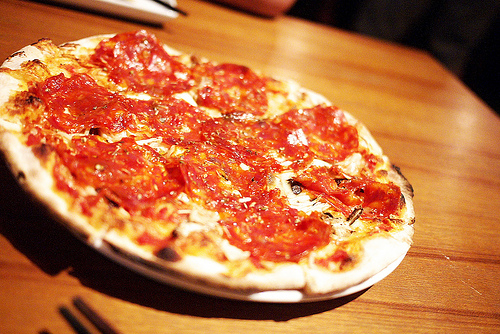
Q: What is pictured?
A: Pizza.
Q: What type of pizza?
A: Pepperoni.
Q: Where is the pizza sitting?
A: On a wooden table.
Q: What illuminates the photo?
A: Indoor lighting.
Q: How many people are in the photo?
A: None.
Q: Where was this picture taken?
A: Maybe a restaurant.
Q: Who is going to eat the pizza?
A: The patrons.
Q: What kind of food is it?
A: Pizza.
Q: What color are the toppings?
A: Red.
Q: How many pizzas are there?
A: One.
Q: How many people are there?
A: None.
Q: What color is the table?
A: Brown.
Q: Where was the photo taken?
A: Inside somewhere.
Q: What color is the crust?
A: Brown.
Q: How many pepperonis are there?
A: More than three.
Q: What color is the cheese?
A: White.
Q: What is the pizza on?
A: Dish.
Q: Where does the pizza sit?
A: On a white dish.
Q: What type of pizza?
A: Pepperoni, cheese and herb.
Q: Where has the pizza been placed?
A: On a plate.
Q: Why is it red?
A: Sauce.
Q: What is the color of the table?
A: Brown.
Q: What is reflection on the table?
A: Light.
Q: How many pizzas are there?
A: 1.